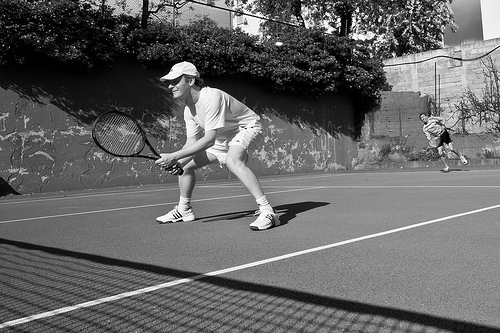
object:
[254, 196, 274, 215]
sock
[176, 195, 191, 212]
sock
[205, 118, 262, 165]
shorts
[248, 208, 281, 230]
shoe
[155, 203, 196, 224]
shoe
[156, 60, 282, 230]
man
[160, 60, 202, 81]
cap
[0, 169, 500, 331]
tennis court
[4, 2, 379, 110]
bushes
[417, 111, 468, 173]
man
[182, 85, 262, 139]
shirt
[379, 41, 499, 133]
wall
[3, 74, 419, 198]
wall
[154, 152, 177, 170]
hand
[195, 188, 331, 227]
shadow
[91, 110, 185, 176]
racket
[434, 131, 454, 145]
black shorts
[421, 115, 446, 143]
striped shirt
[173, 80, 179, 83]
eyes